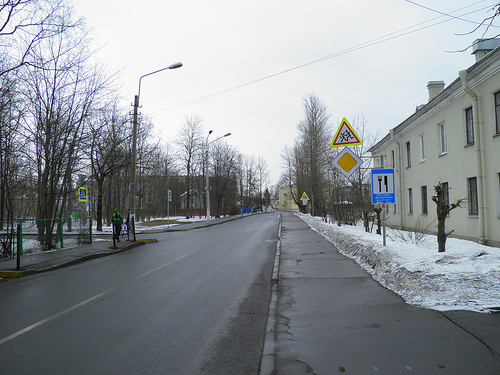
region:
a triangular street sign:
[317, 106, 370, 151]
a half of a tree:
[407, 151, 456, 251]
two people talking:
[98, 188, 142, 245]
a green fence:
[6, 207, 101, 275]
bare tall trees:
[0, 8, 132, 216]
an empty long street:
[152, 191, 297, 358]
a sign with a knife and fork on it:
[363, 161, 401, 245]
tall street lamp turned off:
[122, 47, 184, 227]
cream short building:
[362, 106, 497, 236]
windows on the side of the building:
[399, 102, 486, 167]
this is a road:
[229, 210, 288, 355]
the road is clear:
[115, 246, 237, 361]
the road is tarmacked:
[147, 257, 232, 345]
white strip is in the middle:
[57, 284, 114, 325]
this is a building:
[412, 105, 472, 174]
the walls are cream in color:
[426, 132, 465, 179]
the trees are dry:
[0, 83, 117, 158]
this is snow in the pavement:
[425, 247, 470, 289]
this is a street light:
[153, 54, 190, 86]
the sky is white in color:
[245, 15, 313, 51]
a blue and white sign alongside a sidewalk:
[369, 163, 399, 205]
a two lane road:
[2, 200, 286, 374]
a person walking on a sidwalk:
[107, 206, 127, 244]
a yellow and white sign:
[331, 146, 360, 173]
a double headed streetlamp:
[202, 123, 234, 220]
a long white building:
[358, 54, 497, 235]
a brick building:
[79, 166, 243, 217]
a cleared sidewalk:
[266, 206, 428, 373]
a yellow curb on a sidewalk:
[1, 261, 30, 279]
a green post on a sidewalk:
[10, 222, 33, 270]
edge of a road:
[243, 280, 273, 340]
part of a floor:
[316, 283, 365, 350]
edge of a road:
[51, 265, 79, 271]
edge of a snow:
[383, 223, 429, 316]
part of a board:
[376, 174, 408, 220]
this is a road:
[161, 242, 214, 348]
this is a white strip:
[46, 280, 83, 331]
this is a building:
[416, 107, 478, 176]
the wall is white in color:
[441, 155, 458, 172]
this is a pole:
[126, 127, 138, 204]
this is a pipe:
[468, 100, 493, 207]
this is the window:
[464, 108, 472, 141]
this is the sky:
[186, 9, 383, 101]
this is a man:
[110, 207, 122, 237]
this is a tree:
[303, 95, 333, 192]